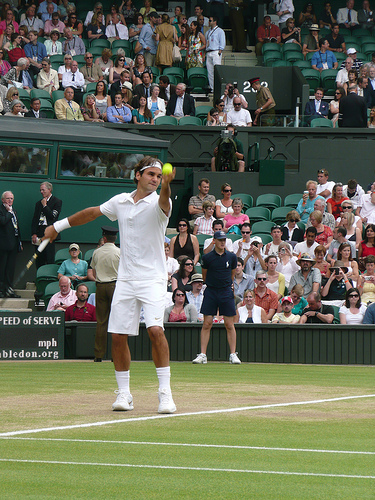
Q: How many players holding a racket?
A: One.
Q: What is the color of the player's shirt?
A: White.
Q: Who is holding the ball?
A: The player.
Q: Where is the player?
A: At the tennis court.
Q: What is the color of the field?
A: Green.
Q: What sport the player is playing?
A: Tennis.